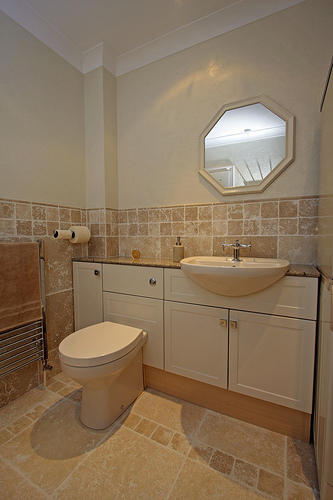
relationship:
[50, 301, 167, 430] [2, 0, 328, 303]
toilet in bathroom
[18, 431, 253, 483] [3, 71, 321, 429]
flooring in bathroom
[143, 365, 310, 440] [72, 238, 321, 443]
base on bottom of sink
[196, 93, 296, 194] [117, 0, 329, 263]
mirror on wall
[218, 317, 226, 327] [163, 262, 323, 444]
handle on cabinet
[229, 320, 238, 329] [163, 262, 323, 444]
handle on cabinet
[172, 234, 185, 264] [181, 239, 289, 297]
lotion dispenser on top of sink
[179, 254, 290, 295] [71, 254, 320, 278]
sink on counter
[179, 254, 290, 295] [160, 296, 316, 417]
sink over cabinet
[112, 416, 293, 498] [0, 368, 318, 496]
lines on floor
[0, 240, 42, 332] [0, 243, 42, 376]
towel on rack